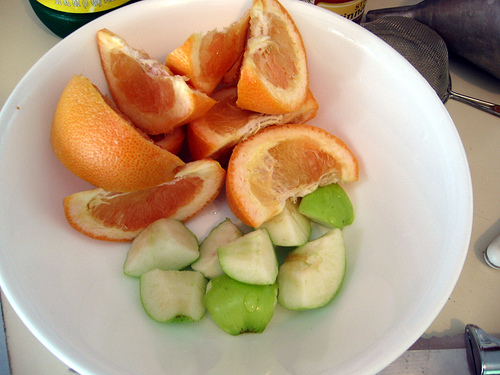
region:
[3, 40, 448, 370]
A white plate with fruit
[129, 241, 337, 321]
An apple cut into chunks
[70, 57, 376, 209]
Orange slices on plate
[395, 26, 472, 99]
A metal strainer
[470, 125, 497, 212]
A beige colored counter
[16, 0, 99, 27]
A brown bottle with yellow label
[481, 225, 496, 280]
A white handle laying on counter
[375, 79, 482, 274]
A large white plate or bowl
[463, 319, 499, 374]
A metal object laying on counter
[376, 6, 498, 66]
A metal funnel laying on counter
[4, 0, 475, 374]
this is a white plate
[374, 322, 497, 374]
thats a silver knife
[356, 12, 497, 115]
thats a silver sifter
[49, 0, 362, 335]
this fruit on a plate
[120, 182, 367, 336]
these are green apples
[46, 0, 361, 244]
these are sliced oranges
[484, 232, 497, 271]
thats a silver handle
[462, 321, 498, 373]
that's the handle on the knife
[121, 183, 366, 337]
these apples are sliced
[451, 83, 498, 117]
thats the handle on the siffter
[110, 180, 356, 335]
Apples in a bowl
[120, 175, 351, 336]
Apples are in a bowl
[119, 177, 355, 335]
Green apples in a bowl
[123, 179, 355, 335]
Green apples are in a bowl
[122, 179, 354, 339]
Granny smith apples in a bowl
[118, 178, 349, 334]
Granny smith apples are in a bowl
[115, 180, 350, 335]
Sliced apples in a bowl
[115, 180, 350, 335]
Sliced apples are in a bowl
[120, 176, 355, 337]
Sliced green apples are in a bowl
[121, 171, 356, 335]
Sliced green apples in a bowl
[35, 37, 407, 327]
a bowl of fruit is on the table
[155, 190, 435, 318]
green apples are sliced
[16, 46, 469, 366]
a white bowl is on the table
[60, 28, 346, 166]
old oranges are in the bowl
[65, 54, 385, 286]
old fruit is sliced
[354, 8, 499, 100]
a strainer is next to the bowl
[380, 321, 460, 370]
a knife is by the bowl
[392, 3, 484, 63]
a sink is by the strainer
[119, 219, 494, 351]
the apples are turning brown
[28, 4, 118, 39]
a jar is by the bowl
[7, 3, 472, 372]
white bowl of fruit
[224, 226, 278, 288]
chopped piece of green apple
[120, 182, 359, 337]
chopped up green apple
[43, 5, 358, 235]
orange slices in bowl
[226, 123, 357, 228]
orange slice in bowl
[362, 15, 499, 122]
hand held strainer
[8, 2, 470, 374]
white bowl of oranges and apples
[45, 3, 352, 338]
oranges and apples in bowl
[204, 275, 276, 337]
rind of green apple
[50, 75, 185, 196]
orange rind of sliced orange